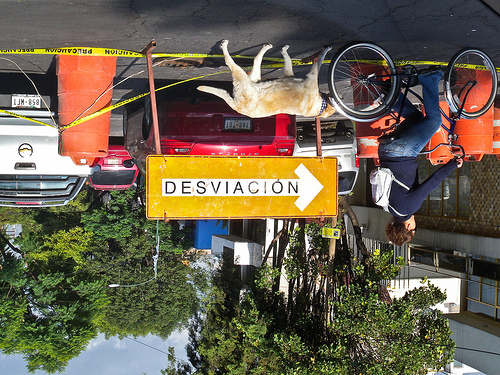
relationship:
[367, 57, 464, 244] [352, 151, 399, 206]
man wearing backpack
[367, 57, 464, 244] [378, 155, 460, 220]
man wearing a shirt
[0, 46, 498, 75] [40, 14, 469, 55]
caution tape on ground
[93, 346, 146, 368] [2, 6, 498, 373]
skies over picture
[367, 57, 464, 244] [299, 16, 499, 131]
man on a bicycle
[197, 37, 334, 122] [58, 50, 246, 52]
dog walking on road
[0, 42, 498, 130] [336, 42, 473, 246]
caution tape separates cars from pedestrian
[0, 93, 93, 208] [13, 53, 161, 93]
car are behind cones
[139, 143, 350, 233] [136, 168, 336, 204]
arrow on a sign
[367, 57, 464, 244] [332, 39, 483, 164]
man riding bicycle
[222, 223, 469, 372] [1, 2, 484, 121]
tree next to road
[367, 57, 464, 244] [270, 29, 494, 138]
man riding bike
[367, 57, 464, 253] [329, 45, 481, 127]
man riding bicycle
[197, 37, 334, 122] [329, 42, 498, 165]
dog behind bicycle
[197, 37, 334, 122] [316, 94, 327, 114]
dog has collar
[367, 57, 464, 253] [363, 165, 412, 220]
man has backpack